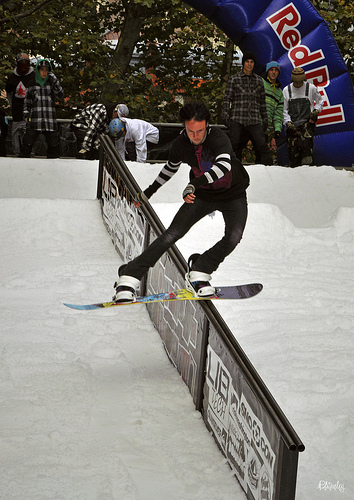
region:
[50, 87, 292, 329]
man on a snowboard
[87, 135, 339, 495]
thin railing running down the slope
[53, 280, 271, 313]
snowboard balancing on the railing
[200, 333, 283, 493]
advertisements on the railing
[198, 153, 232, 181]
black and white stripes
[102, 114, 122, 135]
blue helmet on the head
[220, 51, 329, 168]
group of three people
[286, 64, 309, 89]
head is tilted down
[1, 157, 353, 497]
snow on the ground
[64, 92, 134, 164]
person is bent over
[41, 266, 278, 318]
THIS IS A SNOWBOARD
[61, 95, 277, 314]
THIS GUY IS SNOWBOARDING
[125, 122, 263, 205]
THIS GUY IS WEARING A LONG SLEEVED SHIRT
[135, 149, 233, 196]
THIS GUY HAS STRIPED SLEEVES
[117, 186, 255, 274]
THIS GUY IS WEARING BLACK JEANS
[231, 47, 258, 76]
THIS GUY IS WEARING A BLACK HAT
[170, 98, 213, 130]
THIS GUY HAS BLACK HAIR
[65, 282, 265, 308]
THE SNOWBOARD IS COLORFUL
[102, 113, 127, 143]
THIS GUY IS WEARING A HELMET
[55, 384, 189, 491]
Snow on the background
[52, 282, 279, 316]
A long snow board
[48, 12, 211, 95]
Trees on the background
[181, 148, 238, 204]
Black and white sleeve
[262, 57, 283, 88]
A guy wearing blue bonnet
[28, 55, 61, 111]
A guy with green hood is watching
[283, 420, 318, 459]
Tip of the black steel bars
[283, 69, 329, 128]
A man on white long sleeves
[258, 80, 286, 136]
A green long sleeves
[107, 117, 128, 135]
A blue helmet on the background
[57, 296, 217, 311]
a skating board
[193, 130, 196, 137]
the nose of a man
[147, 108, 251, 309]
a person skating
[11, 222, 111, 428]
white snow on the ground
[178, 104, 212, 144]
the head of a person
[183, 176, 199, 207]
the hand of a man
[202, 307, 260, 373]
a metal rail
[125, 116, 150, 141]
a white piece of clothes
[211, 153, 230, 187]
black and white stripe of a piece of cloth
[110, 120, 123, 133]
a blue helmet on the head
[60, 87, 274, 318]
A snowboarder showing off his skills.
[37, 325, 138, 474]
Plenty of snow on the ground.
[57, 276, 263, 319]
A very colorful snowboard.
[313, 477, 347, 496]
Name of the studio who took the photo.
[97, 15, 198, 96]
Trees in the background.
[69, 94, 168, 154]
Two young men getting ready for their turn.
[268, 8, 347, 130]
Red Bull is a sponsor of the event.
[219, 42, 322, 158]
Three young men watching the boarder.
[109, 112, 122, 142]
Young man wearing a blue helmet.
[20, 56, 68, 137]
Young man wearing a black and white plaid jacket.